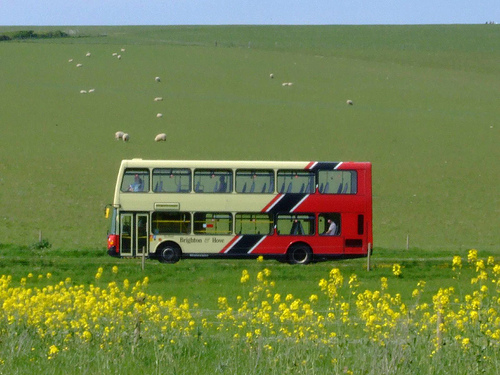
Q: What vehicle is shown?
A: Bus.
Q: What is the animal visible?
A: Sheep.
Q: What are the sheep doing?
A: Grazing.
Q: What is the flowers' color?
A: Yellow.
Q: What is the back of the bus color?
A: Red.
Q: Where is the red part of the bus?
A: In back.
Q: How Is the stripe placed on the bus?
A: Diagonal.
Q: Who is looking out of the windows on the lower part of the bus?
A: Passengers.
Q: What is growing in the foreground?
A: Bright yellow flowers.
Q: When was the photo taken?
A: Spring.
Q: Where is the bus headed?
A: To the left.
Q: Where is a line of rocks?
A: In the upper left part of the field.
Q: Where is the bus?
A: In grass.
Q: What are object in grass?
A: Bus.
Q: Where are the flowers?
A: In grass.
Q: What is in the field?
A: Flowers.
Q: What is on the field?
A: A bus.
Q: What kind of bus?
A: A double decker.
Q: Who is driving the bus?
A: A bus driver.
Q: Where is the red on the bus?
A: At the back.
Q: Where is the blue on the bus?
A: In Front of the red.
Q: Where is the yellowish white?
A: In the front of the bus.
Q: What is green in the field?
A: Grass.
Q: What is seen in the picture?
A: Bus.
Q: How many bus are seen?
A: One.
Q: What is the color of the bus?
A: Red,white,and black.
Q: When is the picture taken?
A: Daytime.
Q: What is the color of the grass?
A: Green.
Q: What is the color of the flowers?
A: Yellow.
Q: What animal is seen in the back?
A: Sheep.